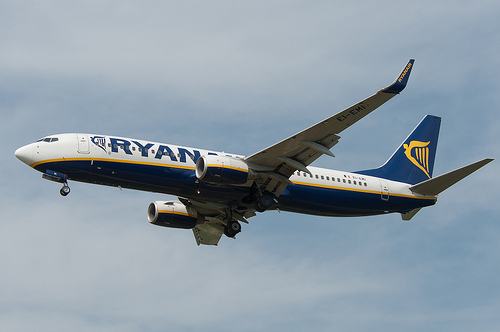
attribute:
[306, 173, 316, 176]
window — a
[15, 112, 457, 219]
plane — a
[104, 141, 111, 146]
window — a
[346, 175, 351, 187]
window — small, glass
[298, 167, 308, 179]
window — small, glass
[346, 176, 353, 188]
glass window — small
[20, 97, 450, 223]
airplane — the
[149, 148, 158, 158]
window — a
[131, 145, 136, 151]
window — a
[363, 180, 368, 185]
window — small, glass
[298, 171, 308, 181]
glass window — small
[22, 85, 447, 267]
airplane — the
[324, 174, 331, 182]
small window — glass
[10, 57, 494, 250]
airplane — the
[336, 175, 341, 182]
window — small, glass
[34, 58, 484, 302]
plane — a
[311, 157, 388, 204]
window — a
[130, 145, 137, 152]
window — a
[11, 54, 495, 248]
plane — blue, white, a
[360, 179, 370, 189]
window — a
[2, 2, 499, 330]
sky — the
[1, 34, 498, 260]
airplane — the